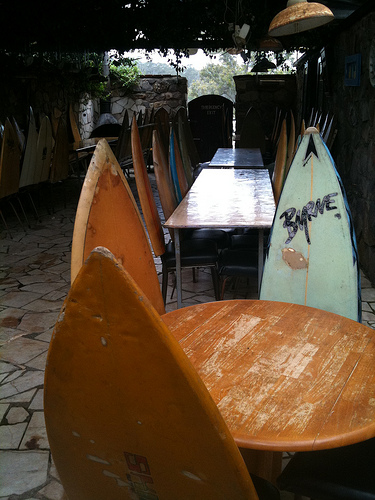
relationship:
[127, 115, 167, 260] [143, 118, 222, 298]
surfboard on chair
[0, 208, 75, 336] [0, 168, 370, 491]
stones on ground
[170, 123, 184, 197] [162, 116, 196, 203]
border on board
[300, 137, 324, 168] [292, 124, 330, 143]
emblem on tip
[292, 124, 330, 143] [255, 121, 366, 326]
tip of surfboard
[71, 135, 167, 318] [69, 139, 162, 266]
backrests made of surfboard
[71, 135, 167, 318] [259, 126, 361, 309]
backrests made of surfboard